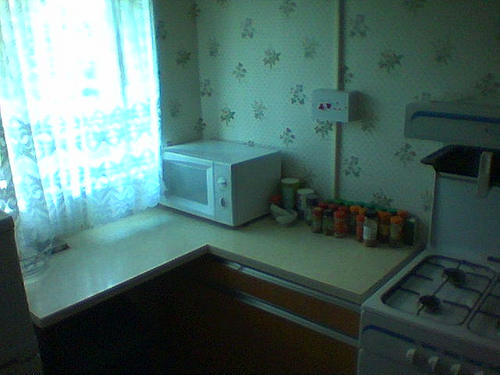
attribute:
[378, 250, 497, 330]
burner — black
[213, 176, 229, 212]
knobs — white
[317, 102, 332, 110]
switches — red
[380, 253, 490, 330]
burner — black, metal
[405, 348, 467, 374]
knobs — white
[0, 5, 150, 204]
window — lighted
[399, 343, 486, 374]
knobs — white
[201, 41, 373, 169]
wallpaper — floral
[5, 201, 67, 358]
fridge — white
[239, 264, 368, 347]
cabinet — wooden, metal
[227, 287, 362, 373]
cabinet — wooden, metal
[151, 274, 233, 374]
cabinet — wooden, metal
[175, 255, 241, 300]
cabinet — wooden, metal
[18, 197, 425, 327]
counter — empty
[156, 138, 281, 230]
microwave — white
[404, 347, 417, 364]
knob — white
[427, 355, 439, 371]
knob — white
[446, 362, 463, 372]
knob — white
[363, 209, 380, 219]
bottle tops — green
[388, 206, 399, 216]
bottle tops — green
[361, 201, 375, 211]
bottle tops — green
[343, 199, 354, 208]
bottle tops — green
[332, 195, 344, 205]
bottle tops — green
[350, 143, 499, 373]
stove — blue, white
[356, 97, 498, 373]
stove — white, blue, old-fashioned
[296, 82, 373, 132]
box — white, metal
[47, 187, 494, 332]
counter — tan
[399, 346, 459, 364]
knobs — white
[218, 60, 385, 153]
wall paper — flowery